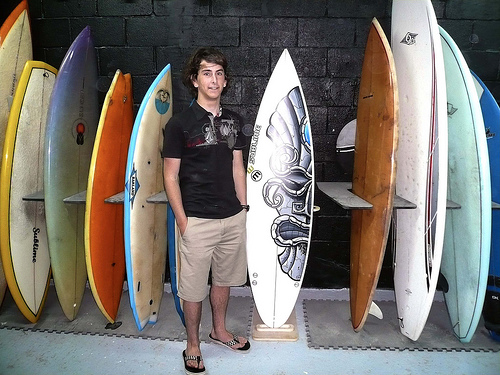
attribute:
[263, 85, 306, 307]
surface — decorated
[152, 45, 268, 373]
man — pictured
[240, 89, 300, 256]
surfboard — white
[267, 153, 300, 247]
picture — airbrushed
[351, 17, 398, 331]
surfboard — not painted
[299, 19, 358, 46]
blocks — black, painted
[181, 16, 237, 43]
blocks — black, painted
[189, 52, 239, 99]
face — smiling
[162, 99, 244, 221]
shirt — collared, black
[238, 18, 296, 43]
block — cinder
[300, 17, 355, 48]
block — cinder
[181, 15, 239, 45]
block — cinder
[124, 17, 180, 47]
block — cinder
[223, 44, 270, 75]
block — cinder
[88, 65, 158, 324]
surfboard — orange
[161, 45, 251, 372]
man — young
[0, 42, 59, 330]
board — white, yellow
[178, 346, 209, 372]
flip flop — pictured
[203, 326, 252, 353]
flip flop — pictured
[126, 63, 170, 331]
board — colorful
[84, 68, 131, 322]
board — colorful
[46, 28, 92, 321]
board — colorful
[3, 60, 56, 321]
board — colorful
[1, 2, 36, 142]
surfboard — white, orange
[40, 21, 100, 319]
surfboard — beige, green, blue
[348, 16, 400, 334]
surfboard — brown